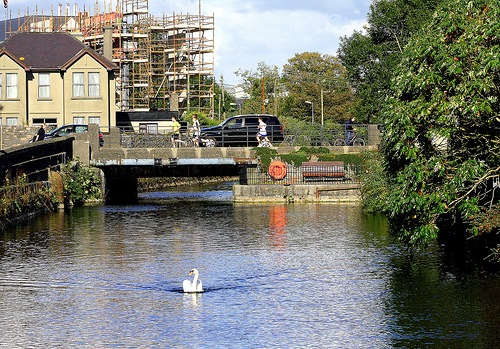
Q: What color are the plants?
A: Green.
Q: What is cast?
A: Shadow.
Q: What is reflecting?
A: Water.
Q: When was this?
A: Daytime.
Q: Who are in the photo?
A: People.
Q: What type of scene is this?
A: Outdoor.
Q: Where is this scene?
A: Waterbody.